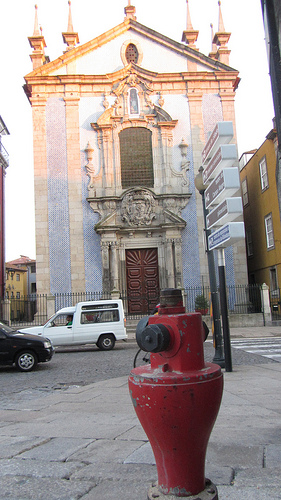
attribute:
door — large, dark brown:
[124, 247, 158, 314]